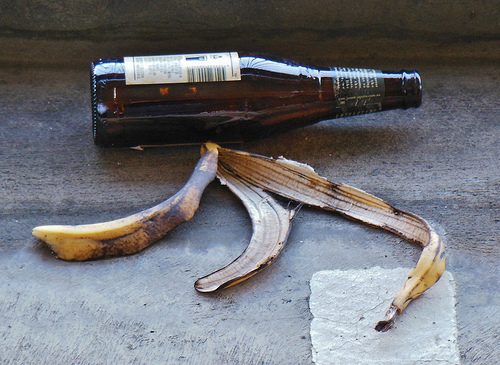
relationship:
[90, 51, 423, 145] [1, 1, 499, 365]
bottle on top of floor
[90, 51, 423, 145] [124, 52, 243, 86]
bottle has label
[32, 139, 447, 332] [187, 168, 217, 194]
peel has part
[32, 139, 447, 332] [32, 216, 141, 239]
peel has part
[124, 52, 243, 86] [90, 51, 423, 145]
label on bottle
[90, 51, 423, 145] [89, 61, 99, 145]
bottle has bottom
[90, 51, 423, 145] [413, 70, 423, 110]
bottle has lip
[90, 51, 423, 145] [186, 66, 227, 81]
bottle has upc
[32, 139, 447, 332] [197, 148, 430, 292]
peel has inside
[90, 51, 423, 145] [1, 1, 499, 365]
bottle on floor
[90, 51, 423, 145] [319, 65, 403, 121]
bottle has neck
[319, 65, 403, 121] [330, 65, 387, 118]
neck has label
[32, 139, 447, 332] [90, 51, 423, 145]
peel in front of bottle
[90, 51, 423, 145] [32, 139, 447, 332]
bottle behind peel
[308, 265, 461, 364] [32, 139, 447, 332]
patch under peel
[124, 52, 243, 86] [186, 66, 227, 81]
label has upc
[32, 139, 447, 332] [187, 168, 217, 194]
peel has spot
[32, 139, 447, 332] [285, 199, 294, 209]
peel has string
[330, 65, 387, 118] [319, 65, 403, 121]
label on neck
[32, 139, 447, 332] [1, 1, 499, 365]
peel on floor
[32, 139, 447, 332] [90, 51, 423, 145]
peel next to bottle